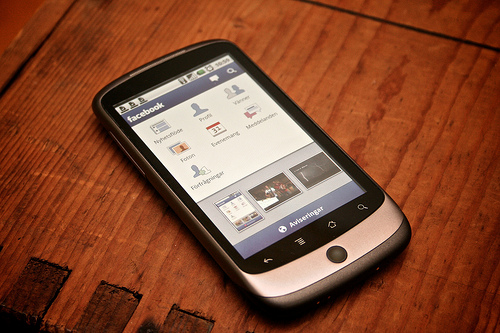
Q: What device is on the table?
A: A smartphone.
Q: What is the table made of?
A: Wood.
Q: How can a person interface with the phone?
A: The screen.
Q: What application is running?
A: Facebook.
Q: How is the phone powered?
A: Electricity.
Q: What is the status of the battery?
A: Full power.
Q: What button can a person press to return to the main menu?
A: The home key.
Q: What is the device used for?
A: Communication.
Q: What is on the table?
A: A cell phone.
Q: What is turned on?
A: A phone.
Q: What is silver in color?
A: The phone.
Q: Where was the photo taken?
A: Next to a table.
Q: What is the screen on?
A: Facebook.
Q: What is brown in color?
A: Table under phone.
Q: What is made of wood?
A: Table.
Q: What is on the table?
A: Dark marks.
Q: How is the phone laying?
A: On its front.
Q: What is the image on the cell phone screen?
A: A webpage.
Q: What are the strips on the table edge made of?
A: Wood.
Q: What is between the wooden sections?
A: A crack.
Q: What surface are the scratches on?
A: Wood.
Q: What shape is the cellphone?
A: Rectangle.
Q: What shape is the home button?
A: Round.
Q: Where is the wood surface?
A: Under the cellphone.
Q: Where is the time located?
A: Top right corner.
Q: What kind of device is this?
A: A cell phone.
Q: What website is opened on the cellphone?
A: Facebook.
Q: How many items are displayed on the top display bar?
A: Eight.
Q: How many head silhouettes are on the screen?
A: Four.